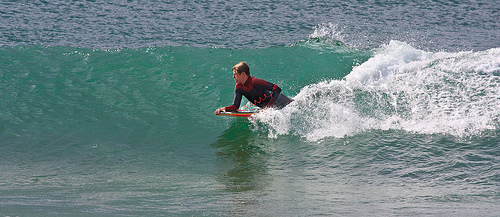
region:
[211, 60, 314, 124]
Surfer in the water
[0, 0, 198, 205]
Mass of ocean water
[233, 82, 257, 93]
Red colored part the clothing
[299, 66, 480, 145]
Splashing water behind the surfer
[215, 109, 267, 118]
Surfboard with red marking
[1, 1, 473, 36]
Settled part of the ocean water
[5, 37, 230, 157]
Big wave of water rolling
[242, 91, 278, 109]
Red cable holding the surfboard to the surfer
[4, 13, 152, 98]
Different shades of blue color of water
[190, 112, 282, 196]
Hazy shadow of surfer formed in the water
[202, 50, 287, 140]
surfer in wetsuit on surfboard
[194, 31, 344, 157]
man surfing in ocean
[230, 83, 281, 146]
line tethered to board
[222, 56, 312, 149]
blonde man in ocean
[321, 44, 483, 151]
white crest of ocean wave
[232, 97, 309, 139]
red board for surfing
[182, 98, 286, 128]
surfer holding onto board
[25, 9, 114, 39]
calm sea behind waves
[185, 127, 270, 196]
reflection of surfer in water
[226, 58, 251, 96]
surfer's hair is wet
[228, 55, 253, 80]
wet flopped over hair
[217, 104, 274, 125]
red a blue surf board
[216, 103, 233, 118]
a hand holding on to a surf board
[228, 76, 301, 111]
a red and blue wet suit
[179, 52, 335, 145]
a man laying down on a surf board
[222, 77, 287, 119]
a red curly safety cord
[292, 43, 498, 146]
a wave crashing into white foam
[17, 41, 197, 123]
a turquoise wave forming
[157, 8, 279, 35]
small choppy waves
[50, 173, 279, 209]
smooth water being pulled into a wave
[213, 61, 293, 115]
A man with brown hair on a surfboard in the water.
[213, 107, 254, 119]
Red surfboard a man is on.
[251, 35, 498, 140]
White wave behind a man on a surfboard.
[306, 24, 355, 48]
Smaller white wave above the surfer to the right.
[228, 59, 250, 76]
Wet brown hair on a man surfing.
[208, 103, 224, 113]
Right hand of a man surfing.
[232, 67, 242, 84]
Side of a white man's face.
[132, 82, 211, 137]
Calm green water in front of a surfing man.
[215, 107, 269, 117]
Surfboard a man is lying on.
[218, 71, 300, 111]
Dark gray and red wetsuit.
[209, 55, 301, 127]
male laying on a surfboard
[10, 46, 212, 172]
green colored water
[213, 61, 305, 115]
man wearing a red and black wet suit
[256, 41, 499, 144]
white colored water behind the man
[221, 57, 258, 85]
man with short hair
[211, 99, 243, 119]
man's right hand holding the surfboard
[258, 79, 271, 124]
man holding surfboard with his left hand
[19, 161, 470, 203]
sun reflecting on the water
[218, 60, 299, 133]
man looking toward the left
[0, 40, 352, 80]
wave coming behind the man